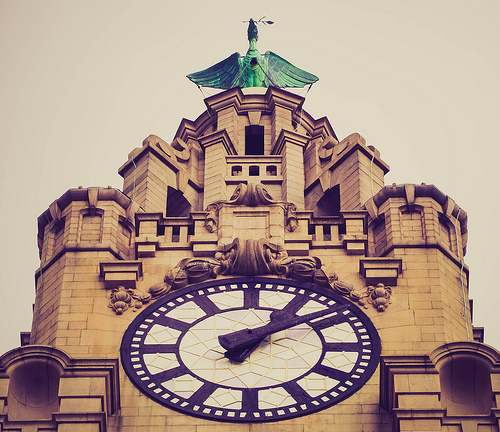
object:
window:
[77, 208, 105, 245]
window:
[400, 204, 426, 241]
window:
[43, 216, 65, 263]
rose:
[243, 16, 274, 27]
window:
[322, 225, 331, 241]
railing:
[226, 155, 283, 184]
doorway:
[245, 125, 265, 156]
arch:
[427, 341, 500, 414]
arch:
[0, 344, 70, 422]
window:
[367, 213, 387, 257]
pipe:
[370, 152, 373, 196]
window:
[116, 215, 132, 257]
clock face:
[142, 289, 359, 412]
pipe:
[33, 212, 50, 345]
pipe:
[455, 207, 470, 341]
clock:
[119, 278, 381, 424]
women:
[158, 143, 348, 247]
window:
[249, 165, 259, 176]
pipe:
[132, 155, 137, 201]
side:
[303, 115, 499, 431]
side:
[1, 185, 143, 431]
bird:
[183, 18, 320, 89]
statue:
[185, 16, 319, 90]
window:
[157, 221, 165, 236]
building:
[0, 88, 498, 428]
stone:
[409, 257, 441, 297]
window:
[437, 211, 457, 256]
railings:
[36, 180, 468, 256]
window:
[266, 165, 277, 175]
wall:
[51, 243, 467, 431]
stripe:
[242, 288, 261, 308]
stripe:
[189, 296, 220, 315]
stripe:
[154, 313, 189, 331]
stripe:
[143, 344, 176, 354]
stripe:
[242, 388, 258, 411]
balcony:
[134, 204, 367, 257]